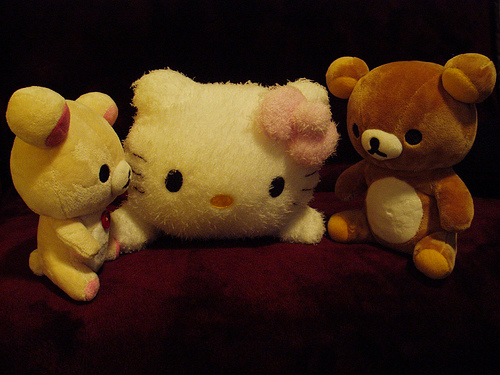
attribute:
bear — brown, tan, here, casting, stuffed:
[340, 61, 480, 259]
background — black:
[6, 9, 412, 81]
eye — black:
[395, 127, 435, 154]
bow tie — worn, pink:
[263, 67, 336, 166]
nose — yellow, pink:
[202, 189, 255, 215]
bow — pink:
[246, 78, 372, 173]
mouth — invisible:
[197, 216, 256, 252]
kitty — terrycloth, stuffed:
[110, 63, 343, 260]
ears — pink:
[132, 52, 225, 113]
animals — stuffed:
[11, 48, 494, 309]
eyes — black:
[348, 115, 462, 163]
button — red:
[93, 206, 120, 241]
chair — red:
[104, 268, 324, 321]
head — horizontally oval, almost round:
[125, 79, 322, 239]